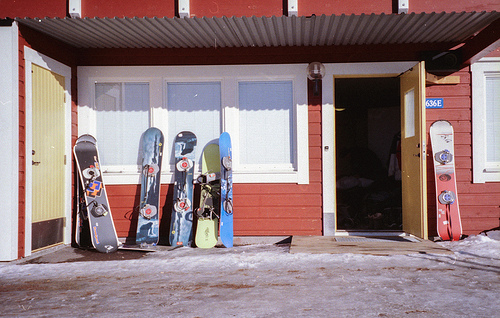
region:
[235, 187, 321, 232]
red siding on exterior of building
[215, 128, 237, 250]
blue snowboard leaning against building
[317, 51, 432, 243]
open wood door with white frame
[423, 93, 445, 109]
address plaque marked 636E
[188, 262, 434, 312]
concrete lightly covered with snow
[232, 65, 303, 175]
windows with shades drawm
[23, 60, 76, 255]
closed yellow door with white frame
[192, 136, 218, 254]
yellow snowboard with black bindings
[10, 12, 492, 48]
tin overhang above doorway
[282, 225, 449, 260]
wooden entrance ramp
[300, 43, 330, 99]
light outside front door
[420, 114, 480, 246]
red and white snow board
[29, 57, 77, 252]
yellow door on front on building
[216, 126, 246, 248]
light blue snow board propped against building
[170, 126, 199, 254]
gray snow board with detailing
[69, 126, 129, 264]
gray snow board with graphics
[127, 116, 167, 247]
gray snow board with graphics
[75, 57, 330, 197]
closed white blinds inside building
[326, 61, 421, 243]
open front door on front of building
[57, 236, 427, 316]
snow and ice on cement in front of building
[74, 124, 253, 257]
Snowboards leaning on outside wall of building.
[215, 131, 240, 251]
Blue snowboard leaning on wall.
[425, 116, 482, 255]
White and red snowboard leaning on wall.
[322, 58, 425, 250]
White frame around door.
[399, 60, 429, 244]
Open door of business.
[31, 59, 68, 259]
Closed door of business.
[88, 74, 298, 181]
Three windows in front of business.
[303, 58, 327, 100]
Outside light mounted next to door.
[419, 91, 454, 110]
Address of business in blue and white.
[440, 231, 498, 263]
Snow piled next to building.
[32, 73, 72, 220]
Most of the door is beige.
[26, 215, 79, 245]
Bottom part of the door is brown.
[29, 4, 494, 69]
Aluminum roof over the doors.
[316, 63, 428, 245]
A door is open.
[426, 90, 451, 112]
636E on the side of the door.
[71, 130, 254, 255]
Snowboards against the window.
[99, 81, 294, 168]
Blinds over the window.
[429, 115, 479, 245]
Snowboard by the open door.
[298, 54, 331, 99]
Light next to the door.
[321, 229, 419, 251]
Matt in front of the door.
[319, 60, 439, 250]
open door on building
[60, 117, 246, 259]
six vertical snowboards with designs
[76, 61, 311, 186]
three windows with white blinds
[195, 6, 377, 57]
metal awning over doorway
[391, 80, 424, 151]
window on open door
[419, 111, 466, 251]
snowboard upright behind door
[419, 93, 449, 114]
blue sign with white number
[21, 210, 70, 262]
metal plate on bottom of door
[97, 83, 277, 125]
shadow of awning on windows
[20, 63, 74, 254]
closed yellow door on building